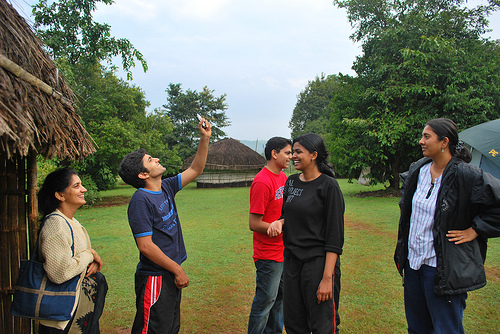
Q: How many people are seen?
A: 5.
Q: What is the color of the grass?
A: Green.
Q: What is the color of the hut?
A: Brown.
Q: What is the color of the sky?
A: Blue.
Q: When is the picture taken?
A: Daytime.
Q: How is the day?
A: Sunny.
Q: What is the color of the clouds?
A: White.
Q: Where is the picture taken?
A: Outside a hut.